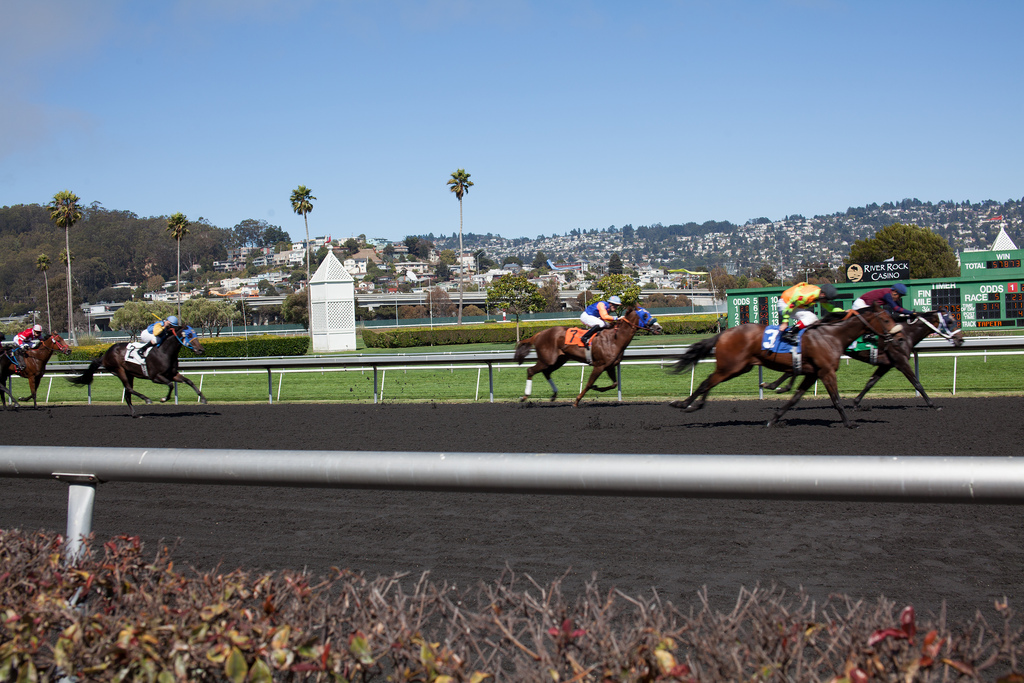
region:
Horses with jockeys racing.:
[0, 270, 969, 397]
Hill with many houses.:
[107, 204, 1012, 294]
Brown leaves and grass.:
[22, 536, 1013, 673]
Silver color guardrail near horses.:
[16, 329, 1022, 406]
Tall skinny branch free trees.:
[46, 188, 192, 347]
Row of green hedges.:
[199, 310, 728, 364]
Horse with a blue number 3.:
[678, 267, 901, 416]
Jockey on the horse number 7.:
[518, 291, 668, 389]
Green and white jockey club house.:
[713, 226, 1023, 340]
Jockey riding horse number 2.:
[69, 295, 200, 403]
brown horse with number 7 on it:
[507, 291, 659, 410]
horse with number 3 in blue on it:
[656, 266, 906, 434]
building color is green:
[703, 207, 1020, 364]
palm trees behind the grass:
[2, 155, 1021, 408]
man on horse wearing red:
[0, 315, 74, 413]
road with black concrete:
[0, 389, 1022, 678]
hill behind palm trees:
[0, 159, 1010, 352]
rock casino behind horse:
[715, 209, 1016, 353]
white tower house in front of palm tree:
[280, 178, 372, 360]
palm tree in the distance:
[435, 162, 487, 246]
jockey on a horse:
[502, 286, 667, 412]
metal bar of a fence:
[48, 422, 1002, 535]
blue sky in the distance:
[545, 15, 968, 140]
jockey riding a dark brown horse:
[133, 303, 179, 360]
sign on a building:
[827, 248, 926, 288]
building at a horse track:
[291, 242, 375, 383]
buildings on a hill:
[630, 215, 854, 261]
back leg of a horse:
[512, 356, 544, 412]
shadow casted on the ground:
[682, 407, 882, 439]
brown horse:
[84, 294, 212, 405]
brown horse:
[520, 280, 660, 417]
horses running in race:
[684, 239, 973, 420]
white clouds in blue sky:
[397, 48, 473, 97]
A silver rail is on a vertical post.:
[3, 446, 1021, 549]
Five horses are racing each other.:
[3, 288, 962, 426]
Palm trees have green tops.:
[28, 171, 475, 273]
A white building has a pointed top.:
[303, 251, 371, 349]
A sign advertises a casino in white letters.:
[839, 253, 915, 285]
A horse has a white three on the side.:
[678, 295, 907, 420]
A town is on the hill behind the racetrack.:
[100, 202, 1021, 317]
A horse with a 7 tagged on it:
[502, 287, 668, 417]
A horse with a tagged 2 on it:
[81, 307, 200, 410]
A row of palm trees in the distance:
[3, 160, 482, 341]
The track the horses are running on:
[2, 383, 1023, 655]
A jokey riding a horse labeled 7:
[568, 287, 638, 357]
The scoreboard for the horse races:
[723, 247, 1021, 375]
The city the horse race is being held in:
[59, 202, 1005, 314]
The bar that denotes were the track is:
[3, 435, 1021, 591]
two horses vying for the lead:
[669, 287, 965, 412]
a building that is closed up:
[305, 246, 357, 355]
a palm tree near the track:
[46, 192, 95, 349]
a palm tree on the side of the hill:
[449, 165, 470, 277]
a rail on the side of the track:
[0, 439, 1018, 501]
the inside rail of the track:
[909, 342, 1021, 391]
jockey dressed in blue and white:
[576, 291, 621, 336]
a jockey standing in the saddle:
[766, 275, 830, 356]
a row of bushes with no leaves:
[0, 530, 1021, 680]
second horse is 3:
[670, 290, 896, 424]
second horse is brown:
[670, 280, 902, 432]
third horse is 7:
[497, 284, 666, 425]